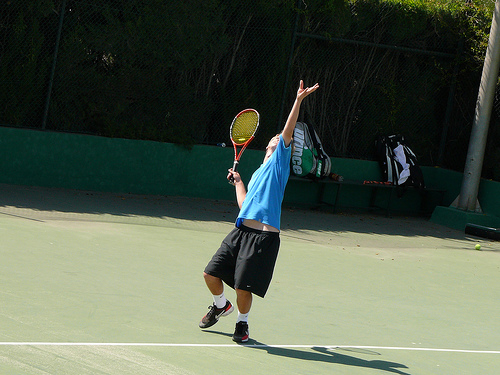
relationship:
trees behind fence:
[73, 7, 374, 87] [81, 19, 378, 125]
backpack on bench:
[360, 129, 419, 176] [296, 177, 435, 209]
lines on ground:
[59, 325, 457, 367] [5, 203, 451, 254]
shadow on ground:
[249, 332, 359, 374] [5, 203, 451, 254]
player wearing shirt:
[198, 80, 318, 343] [238, 153, 291, 237]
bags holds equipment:
[291, 111, 443, 191] [301, 109, 313, 126]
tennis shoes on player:
[201, 298, 258, 337] [198, 80, 318, 343]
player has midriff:
[198, 80, 318, 343] [240, 221, 272, 234]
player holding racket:
[195, 93, 310, 304] [211, 93, 266, 173]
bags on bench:
[291, 111, 443, 191] [296, 177, 435, 209]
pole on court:
[455, 25, 499, 205] [50, 229, 482, 374]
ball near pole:
[460, 234, 489, 254] [455, 25, 499, 205]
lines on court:
[59, 325, 457, 367] [50, 229, 482, 374]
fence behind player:
[81, 19, 378, 125] [195, 93, 310, 304]